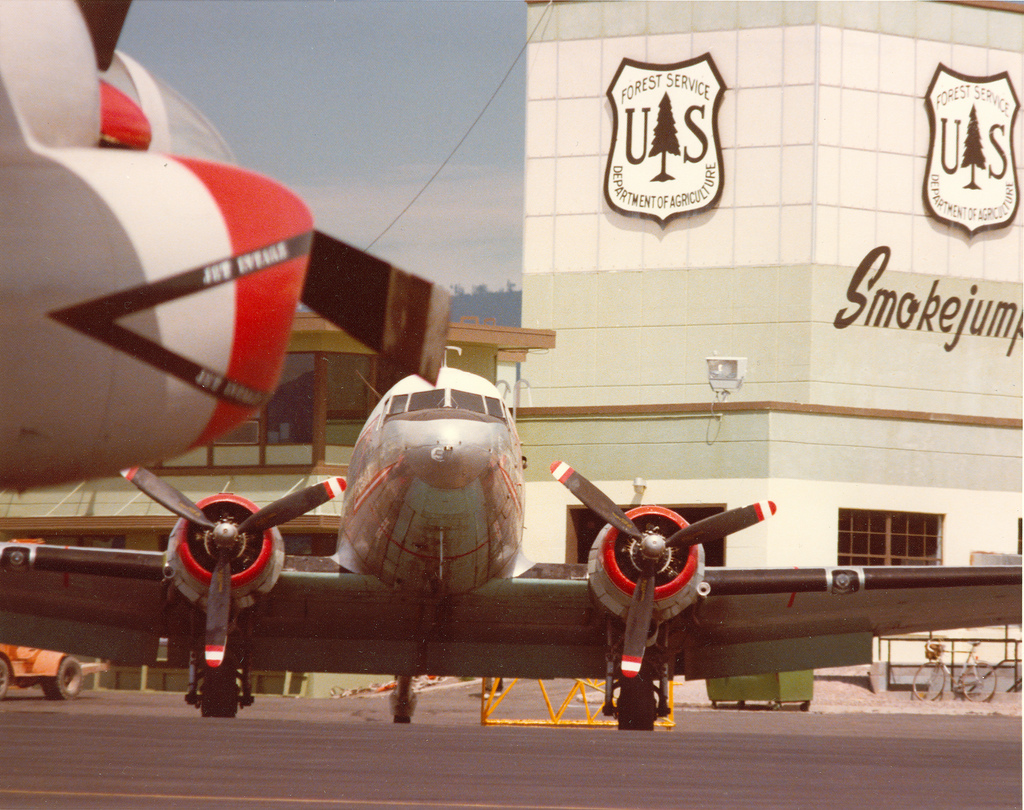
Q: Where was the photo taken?
A: At an airport.